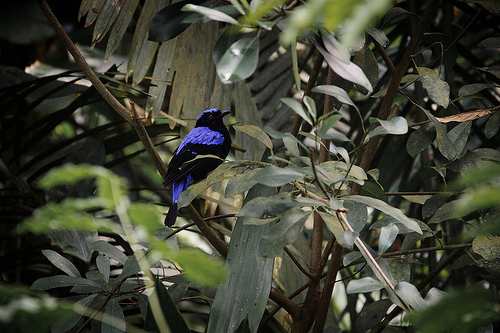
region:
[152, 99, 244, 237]
bird in a tree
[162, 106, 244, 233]
bird with blue feathers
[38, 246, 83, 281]
green leaf on a tree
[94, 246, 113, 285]
green leaf on a tree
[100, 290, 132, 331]
green leaf on a tree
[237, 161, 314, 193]
green leaf on a tree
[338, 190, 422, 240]
green leaf on a tree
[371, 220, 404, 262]
green leaf on a tree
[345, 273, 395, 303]
green leaf on a tree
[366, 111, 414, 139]
green leaf on a tree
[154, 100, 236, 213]
blue bird sitting on branch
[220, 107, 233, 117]
beak of blue bird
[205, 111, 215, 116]
eye of blue bird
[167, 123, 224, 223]
blue feathers of bird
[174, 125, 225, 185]
blue body of blue bird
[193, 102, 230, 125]
head of blue bird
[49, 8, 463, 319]
tree bird is perched on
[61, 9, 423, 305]
branches of tree bird is perched on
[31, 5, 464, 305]
leaves of trees in the background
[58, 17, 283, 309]
branch blue bird is perched on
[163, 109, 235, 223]
A blue bird.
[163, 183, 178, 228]
A tail of a blue bird.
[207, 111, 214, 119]
A red eye of a bird.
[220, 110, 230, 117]
A beak of a blue bird.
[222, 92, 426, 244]
Green leaves.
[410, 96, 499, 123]
A brown leaf.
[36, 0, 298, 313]
A brunch with a bird on.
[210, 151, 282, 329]
Elongated green leaves.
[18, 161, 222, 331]
Green leaves in the foreground.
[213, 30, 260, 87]
A wet green leaf.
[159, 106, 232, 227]
a black and blue bird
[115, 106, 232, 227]
a bird standing on a tree branch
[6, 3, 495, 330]
a black and blue bird in a tree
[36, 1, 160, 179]
a limb on a tree branch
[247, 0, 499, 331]
green leaves on a tree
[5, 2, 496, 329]
a small black and blue bird in a tree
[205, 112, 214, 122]
a bird's red left eye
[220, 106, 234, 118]
the bird's black beak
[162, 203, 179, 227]
a black tail feather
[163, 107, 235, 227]
A black and blue bird.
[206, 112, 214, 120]
Red eye of a black and blue bird.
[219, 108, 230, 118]
Black beak of a blue and black bird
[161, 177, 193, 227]
Back tail feather of a black and blue bird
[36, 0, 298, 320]
Thin brown branch going from middle to upper left.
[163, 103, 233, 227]
A black and blue bird on a branch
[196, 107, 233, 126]
Head of a black and blue bird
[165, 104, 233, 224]
A bird sitting on a branch that is black and blue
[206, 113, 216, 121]
Small red eye of a black and blue bird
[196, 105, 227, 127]
Head of a black and blue bird.